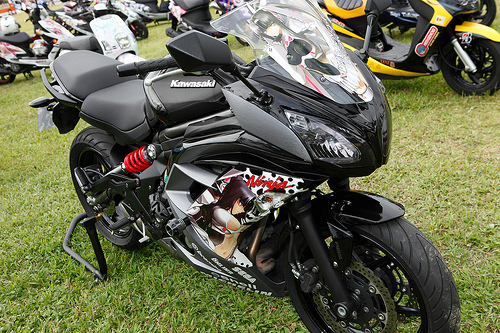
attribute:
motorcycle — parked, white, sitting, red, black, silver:
[29, 0, 462, 327]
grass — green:
[0, 18, 496, 329]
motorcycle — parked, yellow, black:
[322, 1, 499, 95]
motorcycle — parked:
[2, 12, 99, 83]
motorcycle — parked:
[172, 1, 228, 37]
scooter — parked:
[67, 1, 147, 40]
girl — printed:
[255, 12, 368, 105]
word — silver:
[168, 78, 218, 92]